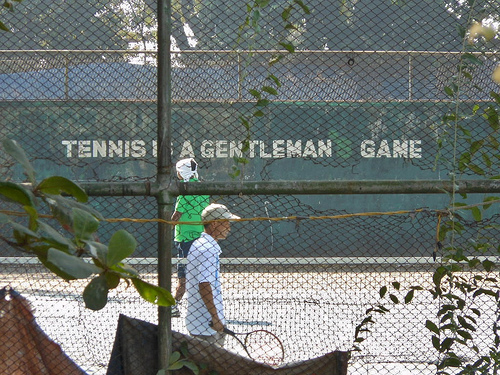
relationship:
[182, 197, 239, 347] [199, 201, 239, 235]
man wearing hat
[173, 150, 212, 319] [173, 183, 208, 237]
woman wearing shirt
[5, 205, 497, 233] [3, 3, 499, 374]
cord running across fence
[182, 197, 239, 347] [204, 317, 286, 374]
man holding racket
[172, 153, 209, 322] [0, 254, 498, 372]
person on court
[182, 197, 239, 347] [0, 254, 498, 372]
man on court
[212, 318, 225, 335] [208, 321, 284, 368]
hand holding racket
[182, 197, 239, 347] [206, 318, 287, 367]
man holding racquet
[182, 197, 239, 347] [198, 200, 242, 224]
man wearing cap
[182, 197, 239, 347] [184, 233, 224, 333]
man wearing shirt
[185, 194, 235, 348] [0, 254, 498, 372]
person on court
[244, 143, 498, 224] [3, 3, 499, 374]
hole in fence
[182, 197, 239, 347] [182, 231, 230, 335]
man in shirt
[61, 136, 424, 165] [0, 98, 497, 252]
letters on wall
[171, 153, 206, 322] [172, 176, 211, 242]
person wearing shirt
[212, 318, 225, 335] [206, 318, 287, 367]
hand holding racquet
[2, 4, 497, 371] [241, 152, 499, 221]
netting has rip